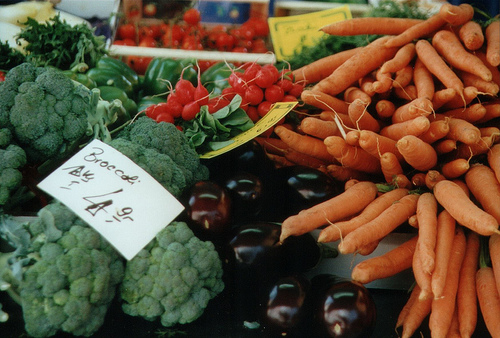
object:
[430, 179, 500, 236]
carrot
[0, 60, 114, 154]
broccoli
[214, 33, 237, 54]
pepper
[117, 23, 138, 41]
strawberry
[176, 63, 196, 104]
radish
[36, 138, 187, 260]
paper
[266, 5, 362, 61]
sign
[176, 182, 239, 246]
eggplant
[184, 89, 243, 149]
kale